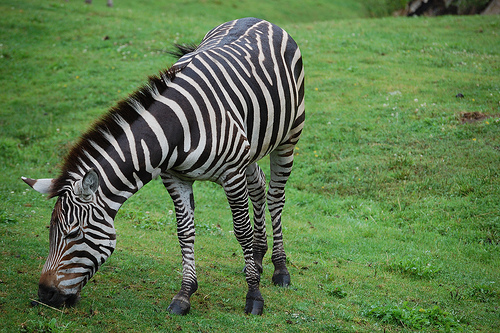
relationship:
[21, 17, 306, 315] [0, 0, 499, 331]
zebra on ground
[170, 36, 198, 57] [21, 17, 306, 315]
tail hairs on zebra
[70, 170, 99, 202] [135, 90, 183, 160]
pointy ear with stripe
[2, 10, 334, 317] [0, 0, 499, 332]
zebra eating grass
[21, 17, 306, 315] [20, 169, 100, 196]
zebra has ears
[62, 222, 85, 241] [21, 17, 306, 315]
eye of zebra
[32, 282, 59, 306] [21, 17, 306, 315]
nose of zebra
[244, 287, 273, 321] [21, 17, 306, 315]
foot of zebra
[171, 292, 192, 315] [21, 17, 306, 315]
foot of zebra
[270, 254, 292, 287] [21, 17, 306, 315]
foot of zebra